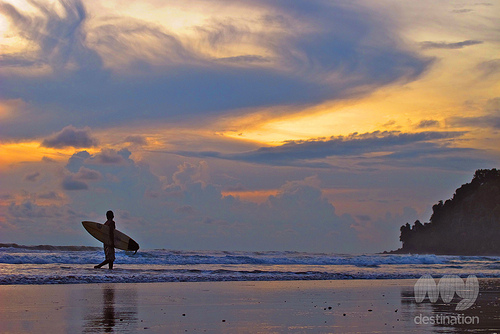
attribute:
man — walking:
[80, 199, 132, 265]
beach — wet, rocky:
[163, 283, 293, 318]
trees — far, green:
[447, 174, 490, 216]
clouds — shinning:
[112, 18, 260, 89]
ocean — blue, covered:
[173, 251, 214, 268]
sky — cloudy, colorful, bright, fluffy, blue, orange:
[187, 5, 396, 70]